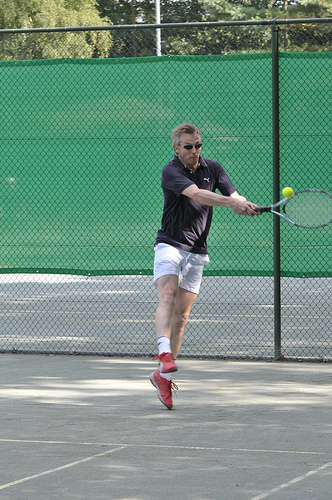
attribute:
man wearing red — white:
[128, 110, 244, 421]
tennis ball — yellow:
[277, 179, 299, 205]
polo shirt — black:
[166, 168, 227, 187]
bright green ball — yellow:
[271, 176, 303, 210]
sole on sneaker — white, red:
[162, 351, 172, 355]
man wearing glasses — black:
[152, 107, 232, 217]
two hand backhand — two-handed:
[232, 188, 259, 229]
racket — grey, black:
[244, 184, 330, 242]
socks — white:
[154, 335, 173, 354]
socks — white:
[157, 359, 173, 379]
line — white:
[77, 441, 125, 465]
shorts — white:
[141, 224, 223, 291]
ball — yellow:
[278, 179, 297, 215]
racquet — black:
[247, 188, 330, 229]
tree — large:
[29, 6, 94, 51]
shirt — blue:
[157, 154, 236, 269]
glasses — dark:
[175, 131, 205, 150]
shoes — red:
[147, 356, 191, 415]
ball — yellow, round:
[278, 183, 297, 204]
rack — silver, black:
[246, 183, 330, 230]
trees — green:
[11, 2, 143, 59]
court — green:
[25, 380, 200, 494]